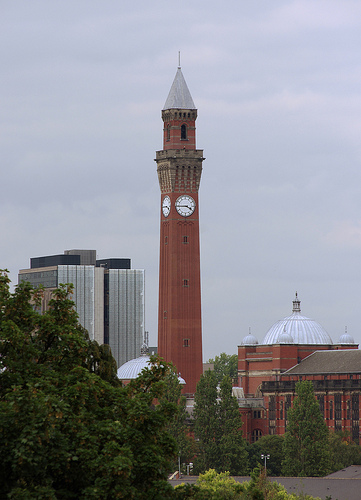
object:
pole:
[177, 51, 182, 67]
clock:
[174, 194, 196, 219]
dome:
[116, 341, 186, 386]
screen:
[174, 194, 195, 218]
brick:
[174, 250, 185, 257]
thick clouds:
[0, 0, 360, 366]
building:
[152, 51, 205, 396]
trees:
[280, 378, 333, 478]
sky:
[0, 0, 360, 366]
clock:
[160, 194, 172, 219]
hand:
[175, 204, 187, 207]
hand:
[187, 205, 196, 212]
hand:
[160, 201, 166, 209]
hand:
[165, 205, 169, 210]